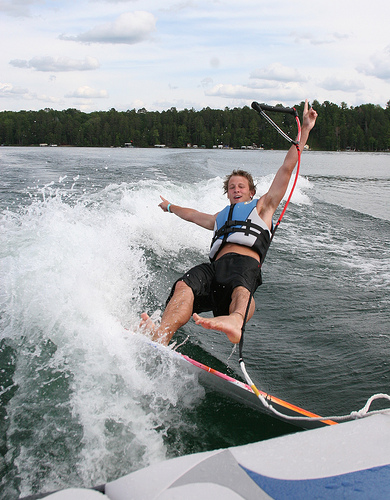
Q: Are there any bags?
A: No, there are no bags.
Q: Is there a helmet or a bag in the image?
A: No, there are no bags or helmets.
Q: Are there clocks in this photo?
A: No, there are no clocks.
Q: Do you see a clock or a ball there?
A: No, there are no clocks or balls.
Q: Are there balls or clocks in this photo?
A: No, there are no clocks or balls.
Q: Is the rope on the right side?
A: Yes, the rope is on the right of the image.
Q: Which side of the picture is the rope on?
A: The rope is on the right of the image.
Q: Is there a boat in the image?
A: Yes, there is a boat.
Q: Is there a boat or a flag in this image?
A: Yes, there is a boat.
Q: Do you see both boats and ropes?
A: Yes, there are both a boat and a rope.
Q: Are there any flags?
A: No, there are no flags.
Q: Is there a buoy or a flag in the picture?
A: No, there are no flags or buoys.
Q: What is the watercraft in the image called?
A: The watercraft is a boat.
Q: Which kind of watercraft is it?
A: The watercraft is a boat.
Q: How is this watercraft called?
A: That is a boat.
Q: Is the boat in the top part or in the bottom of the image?
A: The boat is in the bottom of the image.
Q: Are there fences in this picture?
A: No, there are no fences.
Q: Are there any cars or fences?
A: No, there are no fences or cars.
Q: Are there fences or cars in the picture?
A: No, there are no fences or cars.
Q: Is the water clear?
A: Yes, the water is clear.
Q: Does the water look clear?
A: Yes, the water is clear.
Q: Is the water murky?
A: No, the water is clear.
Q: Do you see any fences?
A: No, there are no fences.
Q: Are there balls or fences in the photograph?
A: No, there are no fences or balls.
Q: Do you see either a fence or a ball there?
A: No, there are no fences or balls.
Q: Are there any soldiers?
A: No, there are no soldiers.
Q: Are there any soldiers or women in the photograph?
A: No, there are no soldiers or women.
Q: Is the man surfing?
A: Yes, the man is surfing.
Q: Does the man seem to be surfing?
A: Yes, the man is surfing.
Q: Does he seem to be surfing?
A: Yes, the man is surfing.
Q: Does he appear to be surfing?
A: Yes, the man is surfing.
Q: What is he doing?
A: The man is surfing.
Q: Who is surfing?
A: The man is surfing.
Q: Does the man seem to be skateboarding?
A: No, the man is surfing.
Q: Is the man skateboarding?
A: No, the man is surfing.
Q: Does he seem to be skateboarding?
A: No, the man is surfing.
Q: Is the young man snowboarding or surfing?
A: The man is surfing.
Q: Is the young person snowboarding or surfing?
A: The man is surfing.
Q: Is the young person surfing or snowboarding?
A: The man is surfing.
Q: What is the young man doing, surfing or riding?
A: The man is surfing.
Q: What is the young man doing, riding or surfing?
A: The man is surfing.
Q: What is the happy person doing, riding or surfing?
A: The man is surfing.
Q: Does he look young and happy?
A: Yes, the man is young and happy.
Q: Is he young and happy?
A: Yes, the man is young and happy.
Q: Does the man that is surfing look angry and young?
A: No, the man is young but happy.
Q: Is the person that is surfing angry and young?
A: No, the man is young but happy.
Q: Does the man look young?
A: Yes, the man is young.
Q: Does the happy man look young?
A: Yes, the man is young.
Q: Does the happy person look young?
A: Yes, the man is young.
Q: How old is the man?
A: The man is young.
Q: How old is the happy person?
A: The man is young.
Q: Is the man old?
A: No, the man is young.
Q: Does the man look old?
A: No, the man is young.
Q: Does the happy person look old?
A: No, the man is young.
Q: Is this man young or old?
A: The man is young.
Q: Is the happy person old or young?
A: The man is young.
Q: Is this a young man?
A: Yes, this is a young man.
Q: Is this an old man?
A: No, this is a young man.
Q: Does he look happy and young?
A: Yes, the man is happy and young.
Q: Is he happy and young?
A: Yes, the man is happy and young.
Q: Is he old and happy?
A: No, the man is happy but young.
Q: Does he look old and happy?
A: No, the man is happy but young.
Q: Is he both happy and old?
A: No, the man is happy but young.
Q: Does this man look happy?
A: Yes, the man is happy.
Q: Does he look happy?
A: Yes, the man is happy.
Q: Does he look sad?
A: No, the man is happy.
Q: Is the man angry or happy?
A: The man is happy.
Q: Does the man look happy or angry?
A: The man is happy.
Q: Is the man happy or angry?
A: The man is happy.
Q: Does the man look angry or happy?
A: The man is happy.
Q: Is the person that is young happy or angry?
A: The man is happy.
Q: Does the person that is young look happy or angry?
A: The man is happy.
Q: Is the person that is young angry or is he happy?
A: The man is happy.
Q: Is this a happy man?
A: Yes, this is a happy man.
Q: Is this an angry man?
A: No, this is a happy man.